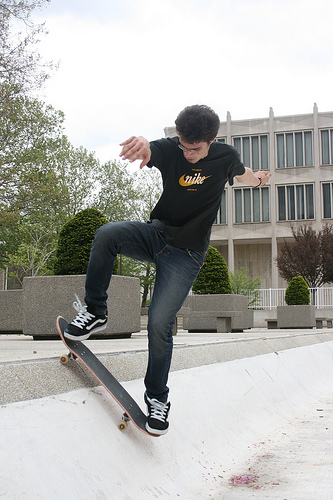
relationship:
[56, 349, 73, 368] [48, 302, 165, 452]
wheel on skateboard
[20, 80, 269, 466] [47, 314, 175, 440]
boy on a skateboard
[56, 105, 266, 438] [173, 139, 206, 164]
boy wearing glasses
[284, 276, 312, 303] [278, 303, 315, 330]
plant growing in block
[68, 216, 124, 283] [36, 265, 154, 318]
plant growing in block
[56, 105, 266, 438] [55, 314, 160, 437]
boy riding skateboard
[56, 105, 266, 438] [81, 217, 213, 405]
boy wearing jeans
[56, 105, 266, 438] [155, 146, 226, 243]
boy wearing shirt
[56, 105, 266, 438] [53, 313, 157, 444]
boy on skateboard